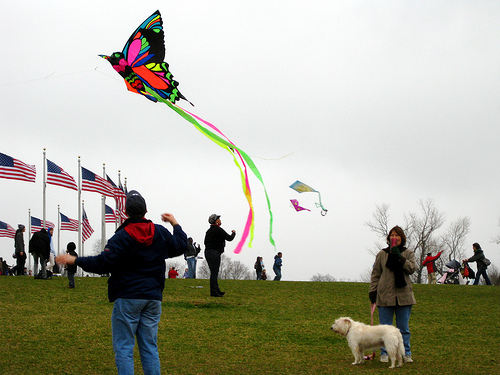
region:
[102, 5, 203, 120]
small kite in the air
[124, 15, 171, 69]
multi colored wing of kite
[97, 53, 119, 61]
small beak of kite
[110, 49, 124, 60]
green eye on kite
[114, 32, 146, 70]
pink part of wing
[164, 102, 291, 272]
green and pink tails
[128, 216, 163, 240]
red hood on jacket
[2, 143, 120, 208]
american flags in background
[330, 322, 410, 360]
small white dog on grass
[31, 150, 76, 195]
flag on a pole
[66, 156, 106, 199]
flag on a pole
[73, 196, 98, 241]
flag on a pole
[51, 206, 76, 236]
flag on a pole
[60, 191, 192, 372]
man wearing a hat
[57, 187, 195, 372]
man wearing blue jeans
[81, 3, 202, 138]
kite in the sky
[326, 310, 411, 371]
A white furry dog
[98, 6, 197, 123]
Kite shaped like a butterfly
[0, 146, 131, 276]
Many red, white and blue American flags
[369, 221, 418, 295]
Woman wearing a black scarf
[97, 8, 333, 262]
Kites are in the air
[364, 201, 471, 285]
A tree with no leaves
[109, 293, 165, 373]
A pair of blue jeans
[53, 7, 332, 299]
People are flying kites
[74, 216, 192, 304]
Dark blue jacket with a red hood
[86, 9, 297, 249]
A multicolored butterfly kite.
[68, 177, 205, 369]
A man in a heavy coat looking up.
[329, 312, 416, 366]
A dog with light fur standing still.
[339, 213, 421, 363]
A woman in a heavy coat holding the dog leash.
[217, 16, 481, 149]
Forecast is grey cloudy skies.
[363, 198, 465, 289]
Trees without leaves in the background.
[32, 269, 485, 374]
Terrain is a grassy green flat field.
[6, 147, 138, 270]
Multiple american flags on metal poles.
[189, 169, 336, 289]
Multiple people flying kites.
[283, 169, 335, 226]
Two kites in the air in the distance.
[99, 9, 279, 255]
A kite shaped like a butterfly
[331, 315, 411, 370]
A white dog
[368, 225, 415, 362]
A woman in a scarf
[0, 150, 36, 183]
An American flag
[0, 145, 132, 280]
A half circle of American flags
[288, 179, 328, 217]
A blue and yellow diamond kite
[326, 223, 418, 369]
A woman walking a dog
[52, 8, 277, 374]
A man flying a kite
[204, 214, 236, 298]
A man dressed in black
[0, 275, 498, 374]
Green and yellow grass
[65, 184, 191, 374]
a person is standing up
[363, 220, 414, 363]
a person is standing up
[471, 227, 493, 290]
a person is standing up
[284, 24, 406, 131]
Large body of cloudy skies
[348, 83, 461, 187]
Large body of cloudy skies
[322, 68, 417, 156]
Large body of cloudy skies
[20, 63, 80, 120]
Large body of cloudy skies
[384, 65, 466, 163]
Large body of cloudy skies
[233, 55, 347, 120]
Large body of cloudy skies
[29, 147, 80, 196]
flag on top of pole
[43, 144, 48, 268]
pole is made of metal